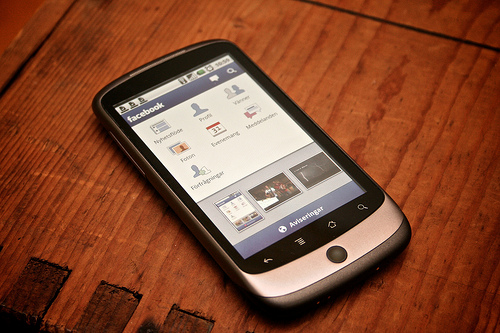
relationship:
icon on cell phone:
[184, 96, 213, 123] [88, 31, 420, 316]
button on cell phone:
[248, 245, 289, 274] [88, 31, 420, 316]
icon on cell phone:
[221, 82, 248, 103] [88, 31, 420, 316]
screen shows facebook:
[113, 53, 365, 259] [133, 76, 340, 239]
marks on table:
[1, 245, 217, 330] [0, 0, 499, 331]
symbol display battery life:
[192, 62, 208, 80] [192, 65, 208, 81]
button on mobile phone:
[322, 213, 343, 236] [82, 27, 422, 325]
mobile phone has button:
[82, 27, 422, 325] [352, 189, 379, 216]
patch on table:
[46, 165, 116, 232] [0, 0, 499, 331]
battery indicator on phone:
[195, 68, 208, 74] [91, 39, 411, 313]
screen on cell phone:
[113, 53, 365, 259] [88, 31, 420, 316]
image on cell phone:
[111, 54, 364, 258] [88, 31, 420, 316]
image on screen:
[111, 54, 364, 258] [113, 53, 365, 259]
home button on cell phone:
[326, 218, 336, 229] [88, 31, 420, 316]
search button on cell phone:
[357, 200, 369, 212] [88, 31, 420, 316]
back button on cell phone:
[262, 254, 275, 265] [88, 31, 420, 316]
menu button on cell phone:
[291, 233, 308, 246] [88, 31, 420, 316]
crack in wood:
[303, 1, 497, 51] [0, 1, 499, 331]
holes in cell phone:
[308, 290, 331, 307] [88, 31, 420, 316]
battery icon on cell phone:
[192, 64, 210, 80] [88, 31, 420, 316]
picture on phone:
[248, 168, 304, 210] [84, 29, 427, 330]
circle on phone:
[324, 242, 349, 267] [91, 39, 411, 313]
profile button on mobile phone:
[188, 98, 210, 120] [82, 27, 422, 325]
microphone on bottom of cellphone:
[321, 241, 348, 265] [90, 36, 413, 316]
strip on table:
[17, 239, 135, 330] [45, 165, 183, 319]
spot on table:
[31, 2, 121, 95] [0, 0, 499, 331]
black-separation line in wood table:
[323, 2, 465, 45] [316, 38, 475, 136]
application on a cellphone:
[204, 115, 237, 146] [116, 30, 408, 320]